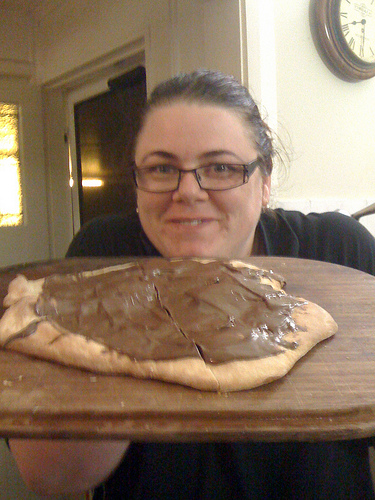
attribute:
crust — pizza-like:
[0, 254, 337, 392]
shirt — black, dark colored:
[63, 206, 374, 498]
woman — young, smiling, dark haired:
[2, 70, 372, 498]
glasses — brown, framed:
[127, 152, 279, 194]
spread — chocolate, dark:
[39, 255, 299, 355]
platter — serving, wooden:
[0, 257, 373, 439]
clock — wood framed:
[308, 0, 374, 81]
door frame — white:
[28, 28, 159, 254]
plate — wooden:
[2, 252, 364, 432]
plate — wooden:
[1, 245, 362, 462]